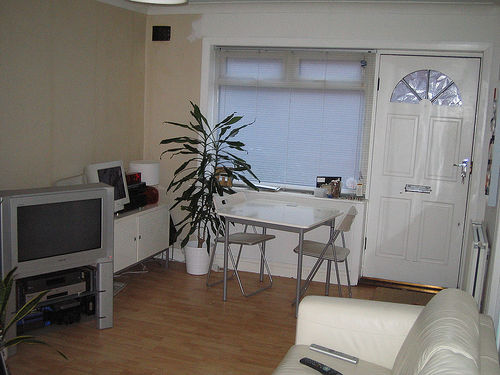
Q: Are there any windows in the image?
A: Yes, there is a window.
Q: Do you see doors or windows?
A: Yes, there is a window.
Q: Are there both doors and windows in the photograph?
A: Yes, there are both a window and a door.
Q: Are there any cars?
A: No, there are no cars.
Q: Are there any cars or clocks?
A: No, there are no cars or clocks.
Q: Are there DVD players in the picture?
A: Yes, there is a DVD player.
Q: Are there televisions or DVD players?
A: Yes, there is a DVD player.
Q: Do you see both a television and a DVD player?
A: Yes, there are both a DVD player and a television.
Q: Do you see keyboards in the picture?
A: No, there are no keyboards.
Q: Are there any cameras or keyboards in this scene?
A: No, there are no keyboards or cameras.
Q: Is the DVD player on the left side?
A: Yes, the DVD player is on the left of the image.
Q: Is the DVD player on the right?
A: No, the DVD player is on the left of the image.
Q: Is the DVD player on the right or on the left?
A: The DVD player is on the left of the image.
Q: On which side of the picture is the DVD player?
A: The DVD player is on the left of the image.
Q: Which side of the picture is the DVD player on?
A: The DVD player is on the left of the image.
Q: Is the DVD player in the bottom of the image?
A: Yes, the DVD player is in the bottom of the image.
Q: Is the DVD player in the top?
A: No, the DVD player is in the bottom of the image.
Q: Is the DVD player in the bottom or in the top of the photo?
A: The DVD player is in the bottom of the image.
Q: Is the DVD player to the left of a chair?
A: Yes, the DVD player is to the left of a chair.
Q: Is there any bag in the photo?
A: No, there are no bags.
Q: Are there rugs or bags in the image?
A: No, there are no bags or rugs.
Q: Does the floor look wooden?
A: Yes, the floor is wooden.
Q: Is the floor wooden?
A: Yes, the floor is wooden.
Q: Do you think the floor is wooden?
A: Yes, the floor is wooden.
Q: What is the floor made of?
A: The floor is made of wood.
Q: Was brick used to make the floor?
A: No, the floor is made of wood.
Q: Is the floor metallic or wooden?
A: The floor is wooden.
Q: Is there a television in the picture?
A: Yes, there is a television.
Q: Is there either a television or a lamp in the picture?
A: Yes, there is a television.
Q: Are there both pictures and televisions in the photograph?
A: No, there is a television but no pictures.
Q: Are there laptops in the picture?
A: No, there are no laptops.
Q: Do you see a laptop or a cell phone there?
A: No, there are no laptops or cell phones.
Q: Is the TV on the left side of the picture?
A: Yes, the TV is on the left of the image.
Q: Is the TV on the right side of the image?
A: No, the TV is on the left of the image.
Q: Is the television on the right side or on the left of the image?
A: The television is on the left of the image.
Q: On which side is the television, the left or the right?
A: The television is on the left of the image.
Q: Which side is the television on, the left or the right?
A: The television is on the left of the image.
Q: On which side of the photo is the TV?
A: The TV is on the left of the image.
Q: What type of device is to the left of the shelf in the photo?
A: The device is a television.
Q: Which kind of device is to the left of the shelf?
A: The device is a television.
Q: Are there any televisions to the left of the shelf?
A: Yes, there is a television to the left of the shelf.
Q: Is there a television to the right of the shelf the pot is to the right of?
A: No, the television is to the left of the shelf.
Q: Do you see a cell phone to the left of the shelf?
A: No, there is a television to the left of the shelf.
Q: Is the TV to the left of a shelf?
A: Yes, the TV is to the left of a shelf.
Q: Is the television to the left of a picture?
A: No, the television is to the left of a shelf.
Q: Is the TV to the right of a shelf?
A: No, the TV is to the left of a shelf.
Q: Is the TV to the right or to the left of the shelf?
A: The TV is to the left of the shelf.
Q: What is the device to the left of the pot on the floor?
A: The device is a television.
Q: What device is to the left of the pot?
A: The device is a television.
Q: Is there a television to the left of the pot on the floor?
A: Yes, there is a television to the left of the pot.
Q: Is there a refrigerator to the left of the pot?
A: No, there is a television to the left of the pot.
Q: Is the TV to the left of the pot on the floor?
A: Yes, the TV is to the left of the pot.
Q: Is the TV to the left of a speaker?
A: No, the TV is to the left of the pot.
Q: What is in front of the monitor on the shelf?
A: The television is in front of the monitor.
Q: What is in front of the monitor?
A: The television is in front of the monitor.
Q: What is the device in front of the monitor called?
A: The device is a television.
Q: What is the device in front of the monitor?
A: The device is a television.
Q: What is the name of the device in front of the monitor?
A: The device is a television.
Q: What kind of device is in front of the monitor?
A: The device is a television.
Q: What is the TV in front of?
A: The TV is in front of the monitor.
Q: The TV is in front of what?
A: The TV is in front of the monitor.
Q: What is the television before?
A: The TV is in front of the monitor.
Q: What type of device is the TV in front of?
A: The TV is in front of the monitor.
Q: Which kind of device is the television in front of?
A: The TV is in front of the monitor.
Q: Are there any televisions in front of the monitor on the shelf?
A: Yes, there is a television in front of the monitor.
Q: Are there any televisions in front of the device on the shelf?
A: Yes, there is a television in front of the monitor.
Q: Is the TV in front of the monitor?
A: Yes, the TV is in front of the monitor.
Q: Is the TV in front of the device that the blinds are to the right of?
A: Yes, the TV is in front of the monitor.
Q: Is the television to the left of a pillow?
A: No, the television is to the left of the chair.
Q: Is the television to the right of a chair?
A: No, the television is to the left of a chair.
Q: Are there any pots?
A: Yes, there is a pot.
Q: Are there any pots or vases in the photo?
A: Yes, there is a pot.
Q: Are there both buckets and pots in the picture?
A: No, there is a pot but no buckets.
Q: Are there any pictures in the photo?
A: No, there are no pictures.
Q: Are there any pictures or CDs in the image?
A: No, there are no pictures or cds.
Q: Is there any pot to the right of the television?
A: Yes, there is a pot to the right of the television.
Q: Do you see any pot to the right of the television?
A: Yes, there is a pot to the right of the television.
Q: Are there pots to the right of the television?
A: Yes, there is a pot to the right of the television.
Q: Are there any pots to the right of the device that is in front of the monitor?
A: Yes, there is a pot to the right of the television.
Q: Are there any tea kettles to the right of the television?
A: No, there is a pot to the right of the television.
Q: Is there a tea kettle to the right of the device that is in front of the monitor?
A: No, there is a pot to the right of the television.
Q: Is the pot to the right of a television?
A: Yes, the pot is to the right of a television.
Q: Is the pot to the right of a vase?
A: No, the pot is to the right of a television.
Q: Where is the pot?
A: The pot is on the floor.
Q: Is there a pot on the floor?
A: Yes, there is a pot on the floor.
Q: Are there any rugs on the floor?
A: No, there is a pot on the floor.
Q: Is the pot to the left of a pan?
A: No, the pot is to the left of the chair.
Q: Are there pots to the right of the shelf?
A: Yes, there is a pot to the right of the shelf.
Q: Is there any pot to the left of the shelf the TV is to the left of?
A: No, the pot is to the right of the shelf.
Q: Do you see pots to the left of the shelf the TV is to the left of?
A: No, the pot is to the right of the shelf.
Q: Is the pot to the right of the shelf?
A: Yes, the pot is to the right of the shelf.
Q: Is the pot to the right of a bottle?
A: No, the pot is to the right of the shelf.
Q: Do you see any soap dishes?
A: No, there are no soap dishes.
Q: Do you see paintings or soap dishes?
A: No, there are no soap dishes or paintings.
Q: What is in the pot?
A: The plant is in the pot.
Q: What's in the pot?
A: The plant is in the pot.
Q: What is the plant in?
A: The plant is in the pot.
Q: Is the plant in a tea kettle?
A: No, the plant is in the pot.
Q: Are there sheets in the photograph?
A: No, there are no sheets.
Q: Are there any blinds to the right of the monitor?
A: Yes, there are blinds to the right of the monitor.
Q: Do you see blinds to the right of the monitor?
A: Yes, there are blinds to the right of the monitor.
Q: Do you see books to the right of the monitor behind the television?
A: No, there are blinds to the right of the monitor.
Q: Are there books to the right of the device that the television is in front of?
A: No, there are blinds to the right of the monitor.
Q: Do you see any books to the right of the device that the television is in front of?
A: No, there are blinds to the right of the monitor.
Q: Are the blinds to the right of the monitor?
A: Yes, the blinds are to the right of the monitor.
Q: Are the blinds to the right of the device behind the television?
A: Yes, the blinds are to the right of the monitor.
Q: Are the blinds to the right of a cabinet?
A: No, the blinds are to the right of the monitor.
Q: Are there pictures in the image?
A: No, there are no pictures.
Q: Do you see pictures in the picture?
A: No, there are no pictures.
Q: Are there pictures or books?
A: No, there are no pictures or books.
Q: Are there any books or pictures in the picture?
A: No, there are no pictures or books.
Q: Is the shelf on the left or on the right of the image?
A: The shelf is on the left of the image.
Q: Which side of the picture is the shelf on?
A: The shelf is on the left of the image.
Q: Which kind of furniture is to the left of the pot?
A: The piece of furniture is a shelf.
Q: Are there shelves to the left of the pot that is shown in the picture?
A: Yes, there is a shelf to the left of the pot.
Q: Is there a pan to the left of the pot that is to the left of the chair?
A: No, there is a shelf to the left of the pot.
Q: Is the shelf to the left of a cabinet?
A: No, the shelf is to the left of the pot.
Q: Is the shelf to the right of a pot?
A: No, the shelf is to the left of a pot.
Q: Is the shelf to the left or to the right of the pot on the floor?
A: The shelf is to the left of the pot.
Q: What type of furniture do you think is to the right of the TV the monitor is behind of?
A: The piece of furniture is a shelf.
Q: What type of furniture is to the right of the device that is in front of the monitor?
A: The piece of furniture is a shelf.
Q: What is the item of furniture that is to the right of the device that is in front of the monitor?
A: The piece of furniture is a shelf.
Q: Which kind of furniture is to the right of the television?
A: The piece of furniture is a shelf.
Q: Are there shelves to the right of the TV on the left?
A: Yes, there is a shelf to the right of the television.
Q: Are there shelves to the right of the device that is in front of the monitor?
A: Yes, there is a shelf to the right of the television.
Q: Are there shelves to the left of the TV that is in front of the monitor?
A: No, the shelf is to the right of the TV.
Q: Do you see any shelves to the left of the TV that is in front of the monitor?
A: No, the shelf is to the right of the TV.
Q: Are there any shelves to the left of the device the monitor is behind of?
A: No, the shelf is to the right of the TV.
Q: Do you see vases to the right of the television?
A: No, there is a shelf to the right of the television.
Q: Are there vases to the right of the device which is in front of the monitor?
A: No, there is a shelf to the right of the television.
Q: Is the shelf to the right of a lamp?
A: No, the shelf is to the right of a television.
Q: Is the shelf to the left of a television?
A: No, the shelf is to the right of a television.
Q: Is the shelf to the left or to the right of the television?
A: The shelf is to the right of the television.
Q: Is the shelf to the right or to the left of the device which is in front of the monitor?
A: The shelf is to the right of the television.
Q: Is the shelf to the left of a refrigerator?
A: No, the shelf is to the left of the chair.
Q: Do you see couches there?
A: Yes, there is a couch.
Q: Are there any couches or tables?
A: Yes, there is a couch.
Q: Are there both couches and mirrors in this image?
A: No, there is a couch but no mirrors.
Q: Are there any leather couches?
A: Yes, there is a couch that is made of leather.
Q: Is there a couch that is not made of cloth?
A: Yes, there is a couch that is made of leather.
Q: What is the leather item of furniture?
A: The piece of furniture is a couch.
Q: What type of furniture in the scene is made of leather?
A: The furniture is a couch.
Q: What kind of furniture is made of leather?
A: The furniture is a couch.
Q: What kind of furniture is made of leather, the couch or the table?
A: The couch is made of leather.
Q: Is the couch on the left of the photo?
A: No, the couch is on the right of the image.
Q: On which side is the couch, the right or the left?
A: The couch is on the right of the image.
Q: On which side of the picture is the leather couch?
A: The couch is on the right of the image.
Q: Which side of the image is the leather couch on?
A: The couch is on the right of the image.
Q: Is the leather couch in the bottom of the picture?
A: Yes, the couch is in the bottom of the image.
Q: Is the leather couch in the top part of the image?
A: No, the couch is in the bottom of the image.